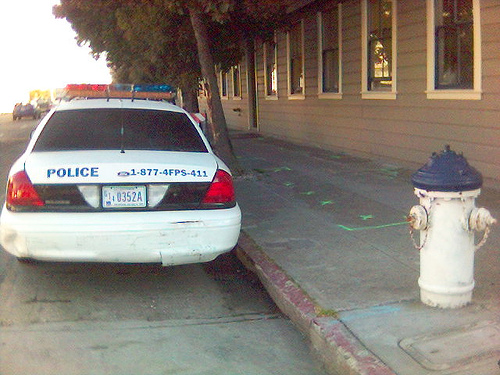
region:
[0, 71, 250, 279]
vehicle parked on a street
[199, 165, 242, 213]
rear tail light on a vehicle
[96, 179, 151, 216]
rear licence plate on a vehicle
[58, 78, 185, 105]
blue and red lights on top of a vehicle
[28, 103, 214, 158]
rear window on a vehicle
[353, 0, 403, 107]
window on a building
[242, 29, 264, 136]
door on a building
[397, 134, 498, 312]
fire hydrant on a sidewalk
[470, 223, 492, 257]
white chain on a fire hydrant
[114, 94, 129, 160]
antenna on the trunk of a vehicle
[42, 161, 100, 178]
blue lettering on white car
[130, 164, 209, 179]
blue lettering on white car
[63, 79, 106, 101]
red light on top of car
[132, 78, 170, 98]
blue light on top of car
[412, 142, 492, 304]
blue and yellow fire hydrant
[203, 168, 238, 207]
red tail light on back of car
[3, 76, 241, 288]
white police car parked by curb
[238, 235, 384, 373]
painted red curb by sidewalk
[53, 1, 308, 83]
trees with green leaves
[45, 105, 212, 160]
rear window of police car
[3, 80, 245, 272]
police car parked at the curb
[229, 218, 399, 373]
curb is a red zone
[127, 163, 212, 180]
police department phone number on the trunk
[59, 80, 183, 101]
red and blue lights atop the police car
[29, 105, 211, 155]
police car has darkly tinted back window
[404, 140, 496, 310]
fire hydrant on the sidewalk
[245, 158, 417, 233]
someone has spray painted green marks on the sidewalk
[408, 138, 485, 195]
the top of the fire hydrant is painted black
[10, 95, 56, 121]
cars visible on the street up ahead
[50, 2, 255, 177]
leafy shade trees line the street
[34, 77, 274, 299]
a police car parked along the curb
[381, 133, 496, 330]
a blue and white fire hydrant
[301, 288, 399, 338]
a blue mark on the sidewalk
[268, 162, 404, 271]
green marks on the sidewalk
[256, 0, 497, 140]
five windows on a building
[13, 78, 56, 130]
cars driving down the street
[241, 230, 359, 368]
a curb painted red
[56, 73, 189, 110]
red and blue lights on top of police car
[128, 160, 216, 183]
number to call the police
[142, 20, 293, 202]
a tree growing out of the sidewalk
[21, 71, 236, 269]
Police car parked on the street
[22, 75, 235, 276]
Police car parked on the street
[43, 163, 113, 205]
Police car parked on the street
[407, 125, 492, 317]
Fire hydrant on the sidewalk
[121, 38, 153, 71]
green leaves on the tree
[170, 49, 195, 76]
green leaves on the tree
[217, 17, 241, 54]
green leaves on the tree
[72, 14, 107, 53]
green leaves on the tree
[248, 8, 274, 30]
green leaves on the tree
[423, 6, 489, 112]
a window on the building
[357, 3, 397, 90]
a window on the building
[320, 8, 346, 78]
a window on the building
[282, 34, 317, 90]
a window on the building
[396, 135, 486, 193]
fire hydrant has blue top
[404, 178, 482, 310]
fire hydrant has white bottom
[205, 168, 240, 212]
car has tailights on it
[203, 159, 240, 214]
car has red tail lights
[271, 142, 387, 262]
sidewalk has green marking on it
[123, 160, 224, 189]
car has numbers on the back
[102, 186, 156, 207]
car has a license plate